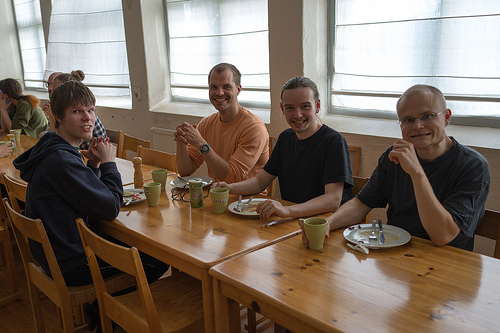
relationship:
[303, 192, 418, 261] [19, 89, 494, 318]
plate on table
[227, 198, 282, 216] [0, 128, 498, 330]
plate on table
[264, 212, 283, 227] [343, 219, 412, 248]
knife on plate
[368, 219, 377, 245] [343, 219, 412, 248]
fork on plate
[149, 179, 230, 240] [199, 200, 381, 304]
shaker on table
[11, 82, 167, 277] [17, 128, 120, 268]
man wears jacket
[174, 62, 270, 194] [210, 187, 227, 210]
man at cup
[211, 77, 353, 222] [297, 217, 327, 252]
man at cup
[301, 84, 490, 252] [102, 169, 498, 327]
man at table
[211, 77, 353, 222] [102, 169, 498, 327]
man at table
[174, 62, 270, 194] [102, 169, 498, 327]
man at table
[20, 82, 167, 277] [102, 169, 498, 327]
man at table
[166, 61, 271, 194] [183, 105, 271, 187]
man wears shirt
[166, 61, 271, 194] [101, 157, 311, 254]
man at table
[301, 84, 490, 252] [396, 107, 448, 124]
man wears glasses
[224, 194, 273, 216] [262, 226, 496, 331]
plate on table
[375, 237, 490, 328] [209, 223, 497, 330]
shadow on table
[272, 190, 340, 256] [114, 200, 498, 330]
cup on table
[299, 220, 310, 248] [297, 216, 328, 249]
fingers around cup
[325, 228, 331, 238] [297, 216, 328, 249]
fingers around cup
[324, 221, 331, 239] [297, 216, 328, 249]
thumb on cup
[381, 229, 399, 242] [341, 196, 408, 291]
sauce on plate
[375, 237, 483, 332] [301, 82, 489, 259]
shadow cast by man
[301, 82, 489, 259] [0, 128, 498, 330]
man sitting at table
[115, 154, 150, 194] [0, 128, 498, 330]
salt on top of table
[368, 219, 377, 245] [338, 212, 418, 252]
fork on top of plate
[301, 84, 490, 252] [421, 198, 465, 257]
man has elbow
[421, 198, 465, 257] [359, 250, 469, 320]
elbow on top of table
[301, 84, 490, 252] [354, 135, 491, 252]
man wearing black shirt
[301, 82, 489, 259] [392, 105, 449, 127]
man wearing glasses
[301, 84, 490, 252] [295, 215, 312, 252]
man has hand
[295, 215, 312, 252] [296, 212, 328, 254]
hand on cup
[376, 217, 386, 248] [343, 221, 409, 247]
knife on top of plate.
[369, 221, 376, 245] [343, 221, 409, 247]
fork on top of plate.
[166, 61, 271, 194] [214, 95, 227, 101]
man has smile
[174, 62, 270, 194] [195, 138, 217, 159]
man wearing watch.